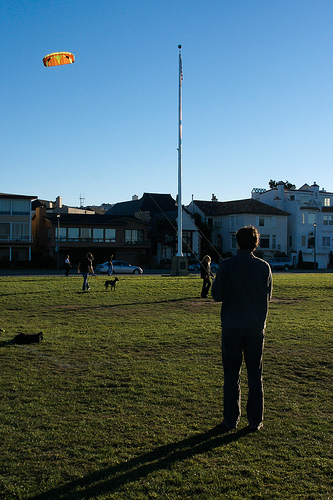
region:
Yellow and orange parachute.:
[37, 49, 76, 68]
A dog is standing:
[103, 274, 123, 294]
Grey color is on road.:
[97, 257, 151, 277]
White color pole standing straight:
[176, 42, 185, 275]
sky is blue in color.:
[195, 22, 328, 154]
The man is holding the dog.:
[76, 252, 121, 292]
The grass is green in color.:
[48, 307, 201, 408]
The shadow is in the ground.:
[20, 427, 269, 497]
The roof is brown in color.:
[190, 197, 283, 223]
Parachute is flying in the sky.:
[37, 36, 106, 110]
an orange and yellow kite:
[41, 44, 83, 69]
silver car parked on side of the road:
[98, 253, 142, 278]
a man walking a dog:
[76, 250, 125, 297]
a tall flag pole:
[173, 34, 196, 273]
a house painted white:
[212, 183, 331, 260]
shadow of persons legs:
[34, 414, 283, 483]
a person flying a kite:
[156, 180, 278, 315]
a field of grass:
[29, 280, 224, 447]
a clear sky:
[10, 121, 321, 201]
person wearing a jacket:
[206, 220, 275, 335]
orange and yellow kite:
[40, 49, 72, 67]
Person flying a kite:
[208, 221, 269, 430]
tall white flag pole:
[174, 40, 181, 253]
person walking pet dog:
[74, 248, 93, 288]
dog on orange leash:
[93, 273, 117, 288]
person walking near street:
[100, 250, 114, 272]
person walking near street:
[61, 251, 67, 271]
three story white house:
[271, 182, 328, 267]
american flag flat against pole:
[175, 50, 185, 96]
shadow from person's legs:
[17, 429, 261, 499]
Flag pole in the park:
[176, 45, 185, 274]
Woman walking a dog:
[75, 252, 120, 291]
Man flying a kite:
[41, 48, 280, 430]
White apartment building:
[249, 177, 332, 266]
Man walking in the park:
[96, 252, 146, 275]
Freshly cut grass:
[51, 297, 180, 414]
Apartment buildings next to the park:
[5, 193, 147, 273]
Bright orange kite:
[34, 36, 102, 101]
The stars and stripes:
[167, 41, 195, 89]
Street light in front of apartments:
[300, 221, 328, 270]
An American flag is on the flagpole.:
[171, 38, 188, 261]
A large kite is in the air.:
[31, 46, 90, 77]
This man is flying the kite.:
[217, 218, 269, 442]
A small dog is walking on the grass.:
[99, 273, 122, 293]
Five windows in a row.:
[52, 218, 121, 244]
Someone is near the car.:
[98, 257, 145, 275]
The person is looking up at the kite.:
[197, 252, 214, 303]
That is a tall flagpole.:
[172, 40, 187, 287]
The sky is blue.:
[200, 8, 321, 176]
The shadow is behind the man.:
[28, 416, 266, 499]